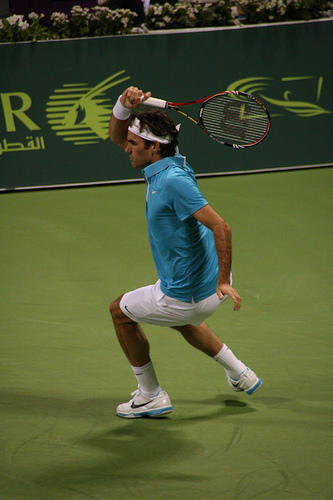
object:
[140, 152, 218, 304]
blue shirt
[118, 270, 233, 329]
shorts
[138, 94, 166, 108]
handle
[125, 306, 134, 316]
logo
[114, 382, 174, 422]
mexican food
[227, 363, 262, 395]
nike sign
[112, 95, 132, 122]
band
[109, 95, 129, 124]
wrist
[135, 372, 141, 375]
nike sign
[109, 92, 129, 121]
wristband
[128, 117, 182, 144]
headband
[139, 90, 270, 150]
racket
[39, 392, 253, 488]
shadow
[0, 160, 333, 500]
court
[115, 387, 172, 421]
nike shoes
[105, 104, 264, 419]
man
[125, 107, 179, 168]
head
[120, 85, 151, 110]
hand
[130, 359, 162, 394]
sock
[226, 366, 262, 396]
shoe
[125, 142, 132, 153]
nose